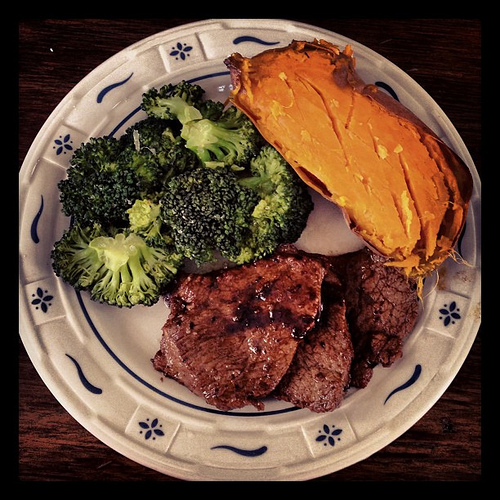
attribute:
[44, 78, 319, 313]
broccoli — cooked, green, piled, fresh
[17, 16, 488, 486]
dish — curved, white, blue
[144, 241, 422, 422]
meat — sliced, cooked, roasted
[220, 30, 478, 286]
sweet potato — baked, half, orange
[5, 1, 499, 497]
table — wooden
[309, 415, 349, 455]
flower — blue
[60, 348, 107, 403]
line — blue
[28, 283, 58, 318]
star — blue